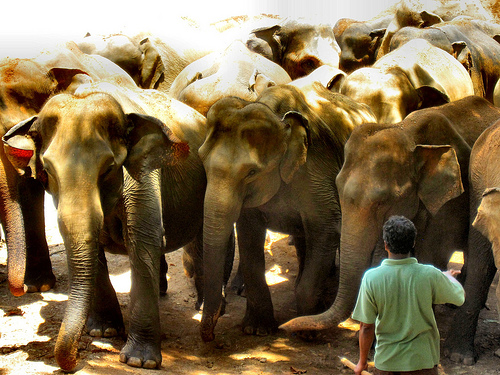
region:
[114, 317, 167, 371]
elephant with brown foot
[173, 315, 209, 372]
shadow under brown elephant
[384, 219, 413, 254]
back of man's head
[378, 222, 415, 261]
man has black hair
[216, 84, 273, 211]
top of elephant's head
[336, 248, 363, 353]
elephant with curved trunk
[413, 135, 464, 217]
elephant has small ear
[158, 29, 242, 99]
light reflecting off elephant's back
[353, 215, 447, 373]
A tan man with black hair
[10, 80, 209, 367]
A large grey elephant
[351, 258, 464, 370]
The lime green shirt of a man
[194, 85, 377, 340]
Another large grey elephant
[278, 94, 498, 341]
A third large grey elephant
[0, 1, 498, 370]
A herd of large grey elephants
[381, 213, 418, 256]
The black hair of a man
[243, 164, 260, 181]
The black left eye of an elephant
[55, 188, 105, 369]
The beige and black trunk of an elephant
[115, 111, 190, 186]
The left ear of an elephant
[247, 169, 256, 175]
The eye of an elephant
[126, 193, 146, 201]
Wrinkles on the leg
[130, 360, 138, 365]
Nail on the foot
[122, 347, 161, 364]
The foot of an elephant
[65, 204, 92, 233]
Trunk reflecting light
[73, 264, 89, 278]
Wrinkles on the trunk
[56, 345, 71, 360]
A coiled up trunk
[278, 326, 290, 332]
The tip of a trunk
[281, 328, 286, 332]
An opening in the trunk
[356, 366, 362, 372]
Hand holding a stick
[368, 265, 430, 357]
the shirt is green in color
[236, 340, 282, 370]
light shine on the floor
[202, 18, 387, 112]
light reflected on the elephants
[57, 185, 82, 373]
the nostrils are long in length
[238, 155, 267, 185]
the eyes are brown in color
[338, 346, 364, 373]
man holding a stick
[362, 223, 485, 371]
man dtanding infront of elephants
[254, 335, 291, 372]
floor is brown in color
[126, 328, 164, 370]
hoof of elephant is black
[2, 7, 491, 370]
large group of elephants all standing very near each other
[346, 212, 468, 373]
man in front of elephant herd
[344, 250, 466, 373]
man wearing a light green tshirt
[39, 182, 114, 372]
a long gray trunk of an elephant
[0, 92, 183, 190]
elephant has long outstretched ears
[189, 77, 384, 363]
elephant is large and gray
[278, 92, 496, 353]
elephant is large and standing among it's herd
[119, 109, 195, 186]
a large elephant ear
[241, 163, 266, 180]
a small elephant eye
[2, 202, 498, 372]
ground is of dirt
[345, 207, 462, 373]
man wearing green shirt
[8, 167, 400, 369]
trunks of the elephants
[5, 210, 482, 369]
shadows of the elephants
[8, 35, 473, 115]
sunlight on the elephants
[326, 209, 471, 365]
man in green shirt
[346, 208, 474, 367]
man in green shirt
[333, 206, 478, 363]
man in green shirt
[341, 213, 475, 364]
man in green shirt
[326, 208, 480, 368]
man in green shirt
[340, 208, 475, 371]
man in green shirt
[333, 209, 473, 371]
man in green shirt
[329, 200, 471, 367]
man in green shirt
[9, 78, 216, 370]
the elephant is facing forward